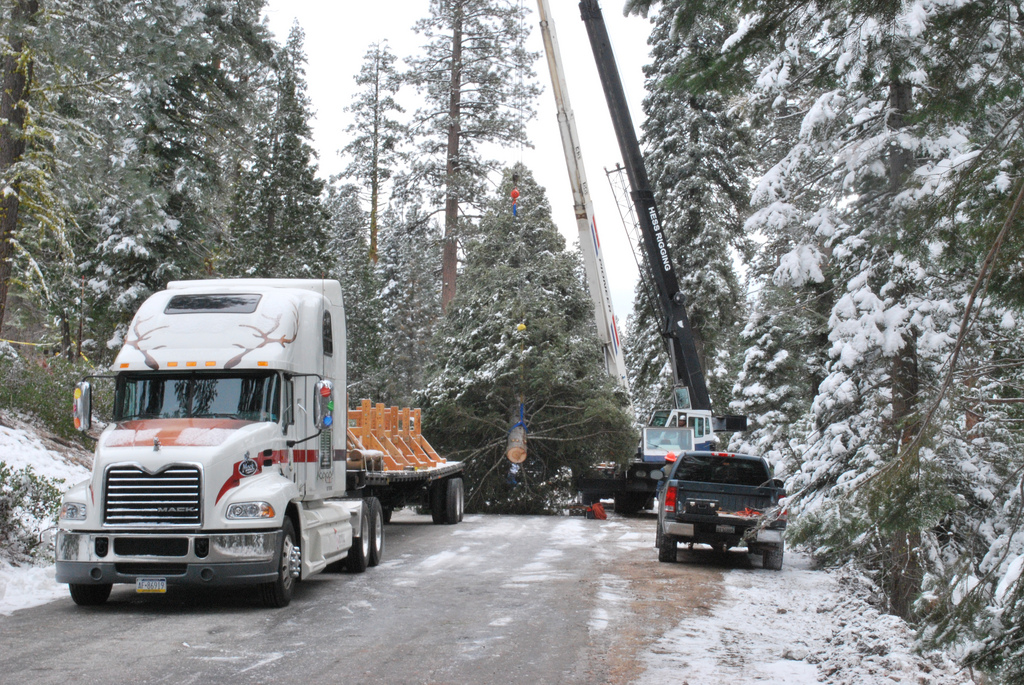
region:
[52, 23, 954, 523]
Pine trees are in side of the road.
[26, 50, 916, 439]
trees are covered with snow.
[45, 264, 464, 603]
Truck is white color.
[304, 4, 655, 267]
Sky is white color.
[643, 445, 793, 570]
car is grey color.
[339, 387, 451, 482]
Blockers are brown color.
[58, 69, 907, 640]
Day time picture.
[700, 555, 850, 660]
Snow is white color.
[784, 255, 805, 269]
snow on the tree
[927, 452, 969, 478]
snow on the tree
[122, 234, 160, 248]
snow on the tree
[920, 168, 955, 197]
snow on the tree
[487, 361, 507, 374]
snow on the tree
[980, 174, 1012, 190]
snow on the tree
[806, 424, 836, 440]
snow on the tree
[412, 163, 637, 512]
evergreen tree by the snowy road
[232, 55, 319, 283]
evergreen tree by the snowy road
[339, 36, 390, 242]
evergreen tree by the snowy road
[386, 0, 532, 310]
evergreen tree by the snowy road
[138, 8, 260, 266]
evergreen tree by the snowy road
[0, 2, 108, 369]
evergreen tree by the snowy road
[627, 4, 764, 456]
evergreen tree by the snowy road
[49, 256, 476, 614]
Truck on a road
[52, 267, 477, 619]
Truck is on a road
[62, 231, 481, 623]
Truck on a snowy road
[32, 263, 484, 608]
Truck is on a snowy road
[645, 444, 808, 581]
Truck is parked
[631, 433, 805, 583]
Truck on side of the road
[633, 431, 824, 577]
Truck is on side of the road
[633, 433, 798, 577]
Pick up truck is on side of the road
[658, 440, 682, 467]
Man wearing an orange helmet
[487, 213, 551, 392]
A corn shaped coniferous tree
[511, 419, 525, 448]
The trunk of a coniferous tree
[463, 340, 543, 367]
Snow on the leaves of a freshly cut tree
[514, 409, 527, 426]
A blue cord tied around a tree trunk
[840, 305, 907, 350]
Leaves of a tree holding white snow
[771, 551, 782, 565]
Snow sticking on the tire of a pick up truck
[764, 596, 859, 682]
Snow accumulated on the side of the road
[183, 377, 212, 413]
Reflection of a tree on the windshield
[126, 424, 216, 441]
Light reflecting on the hood of a truck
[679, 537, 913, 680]
snow on the ground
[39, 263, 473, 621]
truck on the road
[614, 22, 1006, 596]
snow on the trees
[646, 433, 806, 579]
blue pick up with toolbox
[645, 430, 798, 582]
blue pick up with toolbox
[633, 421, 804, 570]
blue pick up with toolbox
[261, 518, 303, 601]
black tire is round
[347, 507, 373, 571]
black tire is round